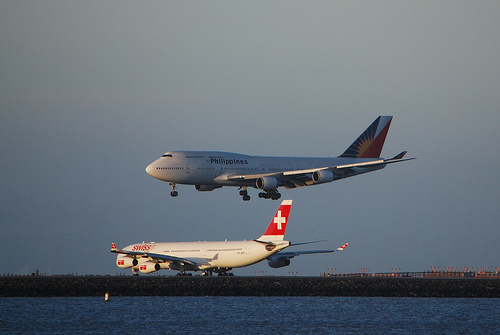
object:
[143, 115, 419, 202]
airplane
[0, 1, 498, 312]
air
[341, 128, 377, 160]
sun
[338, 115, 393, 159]
tail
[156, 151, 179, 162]
cockpit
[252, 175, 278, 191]
engine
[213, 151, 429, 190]
wing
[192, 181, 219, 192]
engine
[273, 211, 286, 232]
cross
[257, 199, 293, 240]
tail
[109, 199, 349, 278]
plane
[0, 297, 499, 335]
ocean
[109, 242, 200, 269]
left wing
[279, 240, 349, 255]
right wing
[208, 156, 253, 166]
philippines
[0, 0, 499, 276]
sky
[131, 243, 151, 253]
swiss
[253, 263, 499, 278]
barriers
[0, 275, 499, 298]
coast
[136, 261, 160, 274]
engine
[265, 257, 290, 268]
engine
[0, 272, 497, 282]
runway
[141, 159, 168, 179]
nose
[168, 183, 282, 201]
landing gear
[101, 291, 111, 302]
buoy